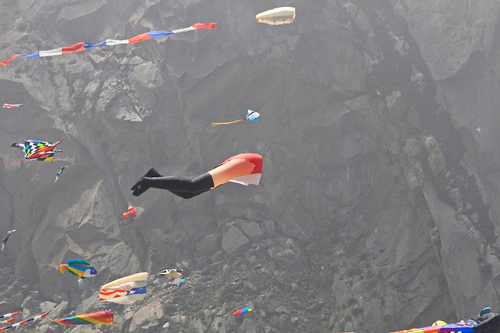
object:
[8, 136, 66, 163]
kite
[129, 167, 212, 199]
leggings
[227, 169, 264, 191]
underside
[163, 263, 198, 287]
kite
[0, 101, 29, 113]
kite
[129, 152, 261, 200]
kite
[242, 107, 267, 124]
kite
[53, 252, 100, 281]
kite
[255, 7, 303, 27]
kite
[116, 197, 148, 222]
kite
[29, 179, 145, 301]
mountain sides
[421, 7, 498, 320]
mountain sides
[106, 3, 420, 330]
mountain sides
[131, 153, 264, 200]
leg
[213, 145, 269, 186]
clothing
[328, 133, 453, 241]
wall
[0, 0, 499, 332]
mountain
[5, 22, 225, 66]
kites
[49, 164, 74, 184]
kites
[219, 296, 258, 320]
kites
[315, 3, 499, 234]
not shown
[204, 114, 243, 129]
kite tail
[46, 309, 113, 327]
kite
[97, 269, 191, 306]
kite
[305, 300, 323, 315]
rock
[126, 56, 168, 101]
rock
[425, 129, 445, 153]
rock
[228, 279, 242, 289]
rock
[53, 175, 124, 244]
rock